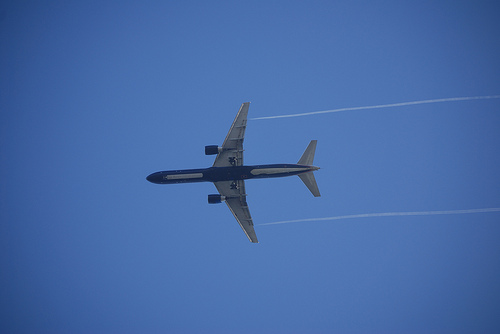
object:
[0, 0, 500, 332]
sky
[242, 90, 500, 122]
streamer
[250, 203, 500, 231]
streamer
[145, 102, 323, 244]
airplane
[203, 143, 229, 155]
engine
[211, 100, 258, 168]
wing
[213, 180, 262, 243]
wing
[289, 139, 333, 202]
tail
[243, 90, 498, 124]
smoke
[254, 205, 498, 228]
smoke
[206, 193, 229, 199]
engine